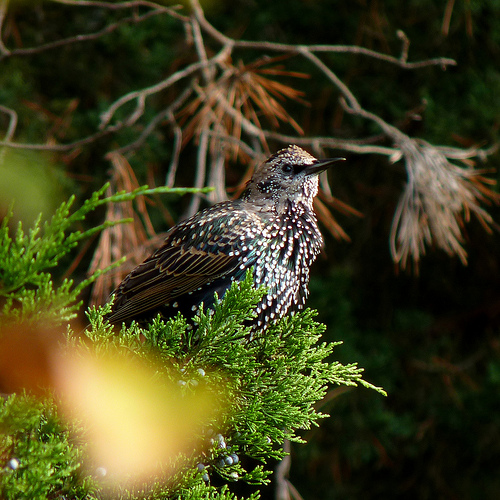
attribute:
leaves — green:
[220, 322, 356, 398]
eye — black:
[277, 159, 295, 179]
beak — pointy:
[315, 151, 347, 174]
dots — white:
[236, 226, 290, 274]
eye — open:
[281, 162, 295, 175]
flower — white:
[342, 102, 494, 254]